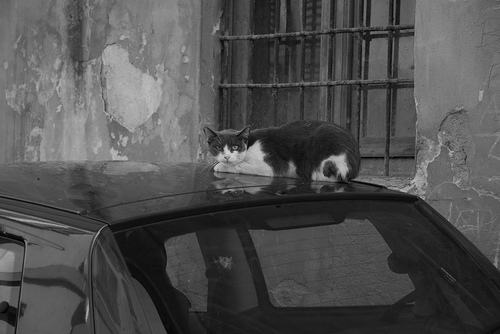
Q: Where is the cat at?
A: Top of car.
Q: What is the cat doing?
A: Resting.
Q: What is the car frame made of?
A: Metal.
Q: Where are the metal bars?
A: On the window.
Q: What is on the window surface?
A: A reflection.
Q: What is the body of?
A: A cat.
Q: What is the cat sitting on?
A: The roof of a car.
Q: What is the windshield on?
A: The front of the car.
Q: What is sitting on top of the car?
A: A cat.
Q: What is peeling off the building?
A: Paint.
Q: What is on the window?
A: Bars.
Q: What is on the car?
A: A cat.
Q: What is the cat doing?
A: Laying down.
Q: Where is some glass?
A: On the car.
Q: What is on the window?
A: Bars.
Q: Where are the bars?
A: On the window.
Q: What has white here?
A: The cat.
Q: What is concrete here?
A: The wall.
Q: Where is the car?
A: Next to the wall.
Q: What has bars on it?
A: The window.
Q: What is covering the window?
A: Bars.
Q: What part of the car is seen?
A: Rear window.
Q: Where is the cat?
A: Top of small car.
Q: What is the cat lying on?
A: Roof of a car.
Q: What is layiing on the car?
A: A cat.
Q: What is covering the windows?
A: Bars.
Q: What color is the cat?
A: Grey and white.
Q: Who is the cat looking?
A: Cameraman.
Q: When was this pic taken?
A: During the day.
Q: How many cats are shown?
A: 1.